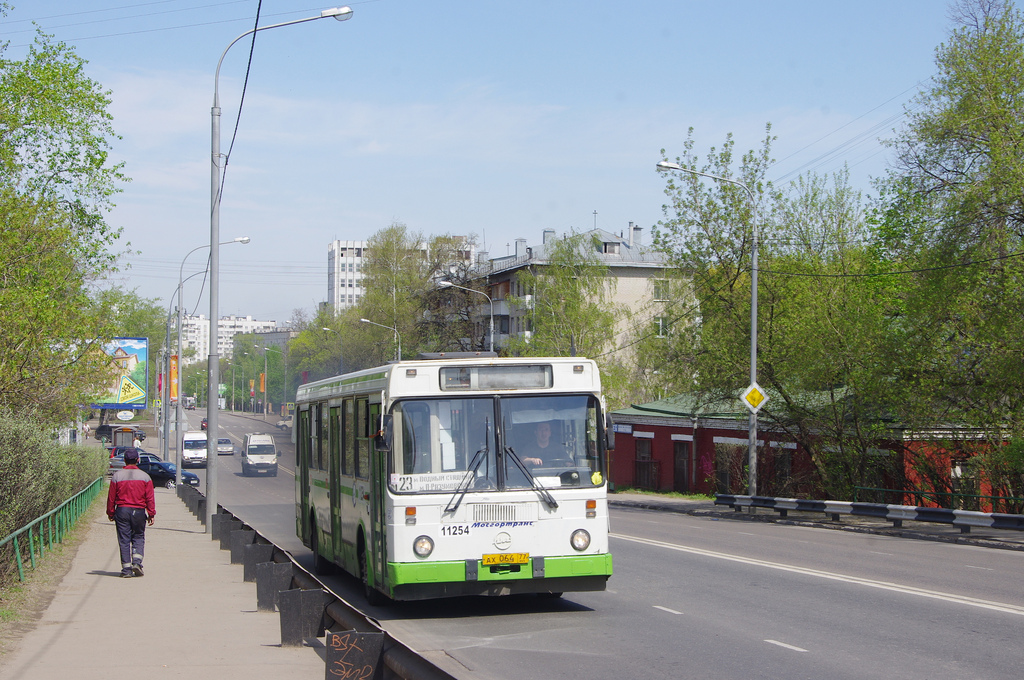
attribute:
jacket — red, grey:
[102, 462, 156, 519]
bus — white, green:
[276, 353, 629, 611]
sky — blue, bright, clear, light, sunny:
[5, 4, 988, 320]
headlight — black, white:
[564, 524, 600, 555]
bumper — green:
[383, 540, 614, 597]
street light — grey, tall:
[193, 1, 354, 541]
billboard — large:
[41, 323, 151, 415]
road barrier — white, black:
[699, 479, 1021, 552]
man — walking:
[100, 446, 165, 580]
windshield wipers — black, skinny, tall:
[436, 445, 560, 518]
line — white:
[644, 590, 688, 629]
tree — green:
[0, 6, 116, 525]